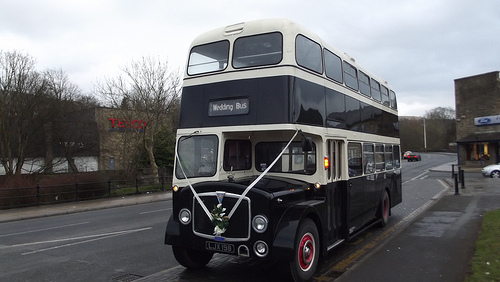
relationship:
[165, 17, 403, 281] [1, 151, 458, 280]
bus on road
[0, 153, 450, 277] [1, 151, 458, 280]
lines on road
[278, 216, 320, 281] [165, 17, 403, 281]
wheel on bus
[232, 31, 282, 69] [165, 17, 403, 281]
window on bus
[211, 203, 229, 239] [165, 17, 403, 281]
flowers on bus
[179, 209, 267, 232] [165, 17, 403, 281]
headlights on bus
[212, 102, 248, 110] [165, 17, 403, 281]
words on bus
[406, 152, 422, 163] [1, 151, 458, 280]
car on road